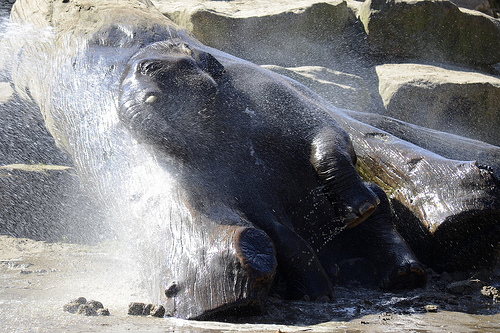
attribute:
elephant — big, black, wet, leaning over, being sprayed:
[118, 39, 426, 302]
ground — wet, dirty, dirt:
[0, 229, 498, 333]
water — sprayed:
[0, 16, 497, 333]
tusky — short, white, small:
[145, 94, 156, 101]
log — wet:
[6, 0, 499, 320]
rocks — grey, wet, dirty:
[0, 1, 498, 238]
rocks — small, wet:
[62, 269, 498, 316]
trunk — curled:
[126, 100, 192, 160]